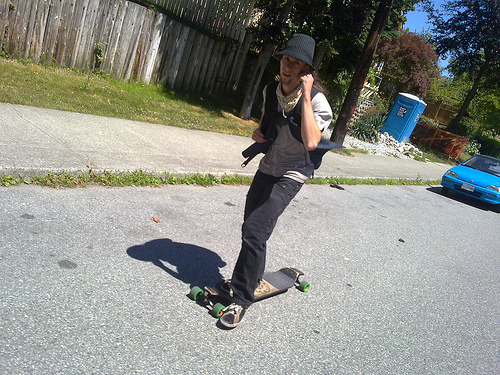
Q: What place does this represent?
A: It represents the pavement.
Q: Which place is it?
A: It is a pavement.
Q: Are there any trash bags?
A: Yes, there is a trash bag.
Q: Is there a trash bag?
A: Yes, there is a trash bag.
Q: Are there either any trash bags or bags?
A: Yes, there is a trash bag.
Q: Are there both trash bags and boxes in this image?
A: No, there is a trash bag but no boxes.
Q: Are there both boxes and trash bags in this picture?
A: No, there is a trash bag but no boxes.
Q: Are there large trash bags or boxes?
A: Yes, there is a large trash bag.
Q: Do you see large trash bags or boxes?
A: Yes, there is a large trash bag.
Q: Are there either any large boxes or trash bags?
A: Yes, there is a large trash bag.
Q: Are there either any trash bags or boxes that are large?
A: Yes, the trash bag is large.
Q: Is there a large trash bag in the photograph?
A: Yes, there is a large trash bag.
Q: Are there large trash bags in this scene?
A: Yes, there is a large trash bag.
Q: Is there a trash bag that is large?
A: Yes, there is a trash bag that is large.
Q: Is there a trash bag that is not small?
A: Yes, there is a large trash bag.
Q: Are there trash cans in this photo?
A: No, there are no trash cans.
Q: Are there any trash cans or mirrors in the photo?
A: No, there are no trash cans or mirrors.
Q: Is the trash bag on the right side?
A: Yes, the trash bag is on the right of the image.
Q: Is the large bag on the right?
A: Yes, the trash bag is on the right of the image.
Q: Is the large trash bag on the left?
A: No, the trash bag is on the right of the image.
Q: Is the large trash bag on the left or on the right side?
A: The trash bag is on the right of the image.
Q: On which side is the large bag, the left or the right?
A: The trash bag is on the right of the image.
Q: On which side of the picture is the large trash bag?
A: The trash bag is on the right of the image.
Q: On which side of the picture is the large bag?
A: The trash bag is on the right of the image.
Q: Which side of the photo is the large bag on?
A: The trash bag is on the right of the image.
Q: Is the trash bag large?
A: Yes, the trash bag is large.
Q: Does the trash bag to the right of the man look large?
A: Yes, the trash bag is large.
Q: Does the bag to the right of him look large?
A: Yes, the trash bag is large.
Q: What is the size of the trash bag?
A: The trash bag is large.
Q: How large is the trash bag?
A: The trash bag is large.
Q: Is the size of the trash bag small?
A: No, the trash bag is large.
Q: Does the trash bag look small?
A: No, the trash bag is large.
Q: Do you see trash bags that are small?
A: No, there is a trash bag but it is large.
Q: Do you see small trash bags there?
A: No, there is a trash bag but it is large.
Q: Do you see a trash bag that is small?
A: No, there is a trash bag but it is large.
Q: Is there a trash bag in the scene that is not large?
A: No, there is a trash bag but it is large.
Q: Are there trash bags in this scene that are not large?
A: No, there is a trash bag but it is large.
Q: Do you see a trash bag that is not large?
A: No, there is a trash bag but it is large.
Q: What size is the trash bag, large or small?
A: The trash bag is large.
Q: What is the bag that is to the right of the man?
A: The bag is a trash bag.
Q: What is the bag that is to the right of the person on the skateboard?
A: The bag is a trash bag.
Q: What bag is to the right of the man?
A: The bag is a trash bag.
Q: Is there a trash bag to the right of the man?
A: Yes, there is a trash bag to the right of the man.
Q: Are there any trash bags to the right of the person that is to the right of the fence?
A: Yes, there is a trash bag to the right of the man.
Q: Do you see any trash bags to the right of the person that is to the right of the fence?
A: Yes, there is a trash bag to the right of the man.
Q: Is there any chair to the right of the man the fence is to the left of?
A: No, there is a trash bag to the right of the man.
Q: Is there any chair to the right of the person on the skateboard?
A: No, there is a trash bag to the right of the man.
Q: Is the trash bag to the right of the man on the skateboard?
A: Yes, the trash bag is to the right of the man.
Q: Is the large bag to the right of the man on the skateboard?
A: Yes, the trash bag is to the right of the man.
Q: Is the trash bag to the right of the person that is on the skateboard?
A: Yes, the trash bag is to the right of the man.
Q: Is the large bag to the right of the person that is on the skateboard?
A: Yes, the trash bag is to the right of the man.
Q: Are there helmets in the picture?
A: No, there are no helmets.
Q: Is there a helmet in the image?
A: No, there are no helmets.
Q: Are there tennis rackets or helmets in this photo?
A: No, there are no helmets or tennis rackets.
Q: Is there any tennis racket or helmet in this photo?
A: No, there are no helmets or rackets.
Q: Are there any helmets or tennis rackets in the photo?
A: No, there are no helmets or tennis rackets.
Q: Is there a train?
A: No, there are no trains.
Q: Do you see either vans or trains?
A: No, there are no trains or vans.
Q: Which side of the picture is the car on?
A: The car is on the right of the image.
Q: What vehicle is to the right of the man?
A: The vehicle is a car.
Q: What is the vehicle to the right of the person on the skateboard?
A: The vehicle is a car.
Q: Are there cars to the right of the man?
A: Yes, there is a car to the right of the man.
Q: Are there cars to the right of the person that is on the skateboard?
A: Yes, there is a car to the right of the man.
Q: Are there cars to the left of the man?
A: No, the car is to the right of the man.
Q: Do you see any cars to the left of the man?
A: No, the car is to the right of the man.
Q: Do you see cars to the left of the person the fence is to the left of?
A: No, the car is to the right of the man.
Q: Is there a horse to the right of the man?
A: No, there is a car to the right of the man.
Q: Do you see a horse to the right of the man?
A: No, there is a car to the right of the man.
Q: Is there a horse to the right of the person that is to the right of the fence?
A: No, there is a car to the right of the man.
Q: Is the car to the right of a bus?
A: No, the car is to the right of the man.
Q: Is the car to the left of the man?
A: No, the car is to the right of the man.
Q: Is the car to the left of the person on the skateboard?
A: No, the car is to the right of the man.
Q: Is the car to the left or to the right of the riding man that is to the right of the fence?
A: The car is to the right of the man.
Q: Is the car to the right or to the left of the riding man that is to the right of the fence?
A: The car is to the right of the man.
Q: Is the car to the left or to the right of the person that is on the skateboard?
A: The car is to the right of the man.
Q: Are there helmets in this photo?
A: No, there are no helmets.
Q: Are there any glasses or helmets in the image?
A: No, there are no helmets or glasses.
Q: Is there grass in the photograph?
A: Yes, there is grass.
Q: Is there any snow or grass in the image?
A: Yes, there is grass.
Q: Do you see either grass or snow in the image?
A: Yes, there is grass.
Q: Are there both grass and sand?
A: No, there is grass but no sand.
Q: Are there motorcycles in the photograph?
A: No, there are no motorcycles.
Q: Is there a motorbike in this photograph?
A: No, there are no motorcycles.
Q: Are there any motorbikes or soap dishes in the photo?
A: No, there are no motorbikes or soap dishes.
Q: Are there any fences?
A: Yes, there is a fence.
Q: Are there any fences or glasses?
A: Yes, there is a fence.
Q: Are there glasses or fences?
A: Yes, there is a fence.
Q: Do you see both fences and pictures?
A: No, there is a fence but no pictures.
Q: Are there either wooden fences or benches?
A: Yes, there is a wood fence.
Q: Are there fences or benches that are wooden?
A: Yes, the fence is wooden.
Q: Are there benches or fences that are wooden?
A: Yes, the fence is wooden.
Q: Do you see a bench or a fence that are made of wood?
A: Yes, the fence is made of wood.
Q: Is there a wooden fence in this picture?
A: Yes, there is a wood fence.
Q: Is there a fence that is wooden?
A: Yes, there is a fence that is wooden.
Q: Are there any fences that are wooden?
A: Yes, there is a fence that is wooden.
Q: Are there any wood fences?
A: Yes, there is a fence that is made of wood.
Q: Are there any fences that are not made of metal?
A: Yes, there is a fence that is made of wood.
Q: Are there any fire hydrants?
A: No, there are no fire hydrants.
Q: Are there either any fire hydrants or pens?
A: No, there are no fire hydrants or pens.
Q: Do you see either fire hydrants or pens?
A: No, there are no fire hydrants or pens.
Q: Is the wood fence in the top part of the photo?
A: Yes, the fence is in the top of the image.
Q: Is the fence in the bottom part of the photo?
A: No, the fence is in the top of the image.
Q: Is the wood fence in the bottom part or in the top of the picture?
A: The fence is in the top of the image.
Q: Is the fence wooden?
A: Yes, the fence is wooden.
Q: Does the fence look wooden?
A: Yes, the fence is wooden.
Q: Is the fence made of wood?
A: Yes, the fence is made of wood.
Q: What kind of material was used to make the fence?
A: The fence is made of wood.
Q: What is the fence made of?
A: The fence is made of wood.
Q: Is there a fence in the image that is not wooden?
A: No, there is a fence but it is wooden.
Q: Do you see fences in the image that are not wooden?
A: No, there is a fence but it is wooden.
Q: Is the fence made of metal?
A: No, the fence is made of wood.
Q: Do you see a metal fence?
A: No, there is a fence but it is made of wood.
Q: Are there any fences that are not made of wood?
A: No, there is a fence but it is made of wood.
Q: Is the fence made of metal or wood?
A: The fence is made of wood.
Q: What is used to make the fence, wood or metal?
A: The fence is made of wood.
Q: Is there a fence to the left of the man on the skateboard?
A: Yes, there is a fence to the left of the man.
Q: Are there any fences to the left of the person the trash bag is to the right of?
A: Yes, there is a fence to the left of the man.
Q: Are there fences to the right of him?
A: No, the fence is to the left of the man.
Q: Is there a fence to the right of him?
A: No, the fence is to the left of the man.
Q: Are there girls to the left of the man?
A: No, there is a fence to the left of the man.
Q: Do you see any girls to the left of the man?
A: No, there is a fence to the left of the man.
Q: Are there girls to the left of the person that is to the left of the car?
A: No, there is a fence to the left of the man.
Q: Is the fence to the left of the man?
A: Yes, the fence is to the left of the man.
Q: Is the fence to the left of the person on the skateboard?
A: Yes, the fence is to the left of the man.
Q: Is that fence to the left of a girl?
A: No, the fence is to the left of the man.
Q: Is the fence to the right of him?
A: No, the fence is to the left of a man.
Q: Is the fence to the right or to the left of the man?
A: The fence is to the left of the man.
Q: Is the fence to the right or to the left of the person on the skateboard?
A: The fence is to the left of the man.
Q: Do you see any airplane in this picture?
A: No, there are no airplanes.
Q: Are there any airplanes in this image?
A: No, there are no airplanes.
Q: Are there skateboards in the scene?
A: Yes, there is a skateboard.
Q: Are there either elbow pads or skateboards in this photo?
A: Yes, there is a skateboard.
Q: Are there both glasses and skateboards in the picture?
A: No, there is a skateboard but no glasses.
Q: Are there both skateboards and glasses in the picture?
A: No, there is a skateboard but no glasses.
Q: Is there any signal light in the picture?
A: No, there are no traffic lights.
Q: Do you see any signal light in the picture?
A: No, there are no traffic lights.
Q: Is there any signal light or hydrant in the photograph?
A: No, there are no traffic lights or fire hydrants.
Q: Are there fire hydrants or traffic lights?
A: No, there are no traffic lights or fire hydrants.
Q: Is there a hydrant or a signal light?
A: No, there are no traffic lights or fire hydrants.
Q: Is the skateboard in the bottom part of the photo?
A: Yes, the skateboard is in the bottom of the image.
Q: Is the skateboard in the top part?
A: No, the skateboard is in the bottom of the image.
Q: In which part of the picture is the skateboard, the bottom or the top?
A: The skateboard is in the bottom of the image.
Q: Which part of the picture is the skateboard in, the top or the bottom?
A: The skateboard is in the bottom of the image.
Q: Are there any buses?
A: No, there are no buses.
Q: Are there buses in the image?
A: No, there are no buses.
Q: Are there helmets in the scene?
A: No, there are no helmets.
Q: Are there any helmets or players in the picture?
A: No, there are no helmets or players.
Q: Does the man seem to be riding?
A: Yes, the man is riding.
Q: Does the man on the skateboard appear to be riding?
A: Yes, the man is riding.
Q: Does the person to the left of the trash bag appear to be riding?
A: Yes, the man is riding.